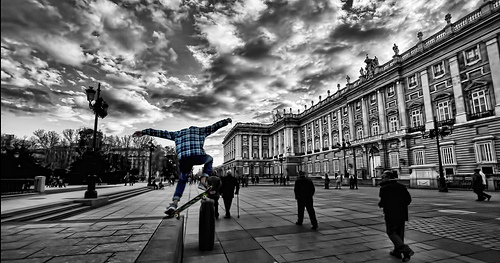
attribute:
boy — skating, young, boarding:
[135, 116, 234, 219]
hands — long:
[133, 116, 233, 136]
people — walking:
[278, 166, 424, 261]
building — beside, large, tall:
[221, 2, 497, 185]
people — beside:
[220, 161, 499, 262]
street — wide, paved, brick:
[188, 157, 500, 262]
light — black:
[428, 124, 452, 192]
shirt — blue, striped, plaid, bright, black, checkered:
[128, 109, 241, 159]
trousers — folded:
[166, 156, 210, 204]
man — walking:
[222, 167, 240, 221]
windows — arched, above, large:
[301, 83, 499, 154]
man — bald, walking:
[380, 164, 414, 261]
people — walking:
[467, 167, 493, 199]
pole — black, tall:
[81, 85, 106, 197]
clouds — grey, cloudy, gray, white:
[0, 3, 492, 142]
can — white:
[36, 174, 46, 196]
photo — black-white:
[0, 0, 498, 262]